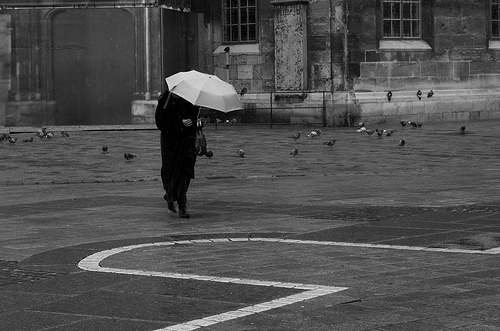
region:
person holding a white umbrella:
[157, 63, 267, 122]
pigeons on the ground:
[271, 129, 377, 169]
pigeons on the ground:
[95, 133, 134, 168]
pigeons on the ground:
[356, 119, 426, 156]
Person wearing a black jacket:
[152, 90, 224, 202]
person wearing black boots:
[157, 183, 199, 233]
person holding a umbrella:
[160, 107, 216, 140]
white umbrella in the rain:
[181, 63, 237, 128]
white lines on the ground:
[95, 204, 252, 327]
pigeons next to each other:
[216, 120, 310, 171]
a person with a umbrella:
[144, 64, 250, 221]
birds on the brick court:
[277, 118, 448, 178]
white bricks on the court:
[113, 219, 383, 304]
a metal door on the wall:
[55, 0, 153, 140]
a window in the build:
[379, 1, 437, 56]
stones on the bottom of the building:
[361, 85, 487, 129]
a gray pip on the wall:
[139, 5, 159, 100]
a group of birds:
[9, 112, 72, 170]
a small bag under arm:
[187, 124, 216, 161]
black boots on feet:
[164, 189, 198, 219]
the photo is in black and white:
[0, 0, 498, 327]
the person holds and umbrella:
[160, 64, 239, 214]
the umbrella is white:
[161, 73, 239, 216]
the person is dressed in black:
[163, 73, 235, 210]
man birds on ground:
[3, 86, 493, 158]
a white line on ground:
[76, 237, 499, 329]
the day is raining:
[3, 0, 496, 330]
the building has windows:
[223, 2, 427, 49]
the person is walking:
[162, 71, 242, 217]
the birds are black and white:
[0, 90, 498, 155]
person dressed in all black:
[151, 83, 216, 221]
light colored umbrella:
[163, 66, 247, 116]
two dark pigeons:
[99, 140, 140, 164]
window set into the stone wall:
[374, 0, 438, 55]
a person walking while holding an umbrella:
[149, 66, 244, 223]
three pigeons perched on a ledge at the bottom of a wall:
[384, 85, 439, 103]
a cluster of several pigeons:
[0, 123, 72, 141]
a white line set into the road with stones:
[74, 228, 499, 328]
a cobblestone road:
[2, 118, 498, 185]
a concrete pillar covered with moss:
[271, 0, 310, 102]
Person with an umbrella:
[149, 70, 246, 223]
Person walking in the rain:
[139, 63, 251, 223]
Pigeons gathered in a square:
[269, 115, 473, 168]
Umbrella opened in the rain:
[160, 63, 244, 120]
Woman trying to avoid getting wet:
[123, 56, 246, 228]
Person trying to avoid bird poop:
[144, 65, 261, 222]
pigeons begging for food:
[288, 76, 454, 143]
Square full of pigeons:
[5, 135, 495, 323]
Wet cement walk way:
[211, 184, 492, 324]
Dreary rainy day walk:
[15, 8, 499, 313]